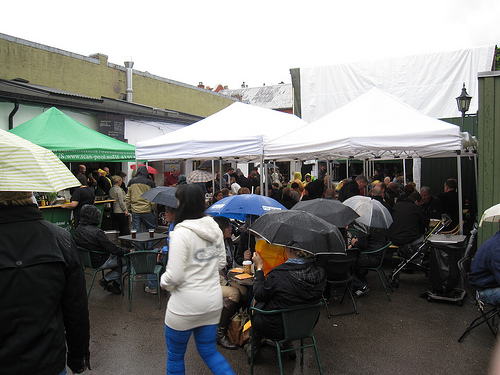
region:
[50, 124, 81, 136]
the umbrella is green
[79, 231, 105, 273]
the person is sitting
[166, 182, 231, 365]
the lady is walking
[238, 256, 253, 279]
the cup is brown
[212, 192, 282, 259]
the person is holding the umbrella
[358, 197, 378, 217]
the umbrella is gray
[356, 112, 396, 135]
the tent is white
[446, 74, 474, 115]
the light is off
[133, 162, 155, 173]
the umbrella is red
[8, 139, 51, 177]
the umbrella has stripes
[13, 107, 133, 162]
green pop up tent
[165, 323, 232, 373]
tight blue pants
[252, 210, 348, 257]
black umbrella is open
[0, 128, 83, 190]
horizontal stripes on the umbrella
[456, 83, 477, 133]
black light is not on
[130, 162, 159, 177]
small red umbrella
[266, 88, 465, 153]
white pop up tent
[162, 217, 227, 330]
white hooded sweatshirt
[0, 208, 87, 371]
black rain jacket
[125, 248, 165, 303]
empty outdoor chair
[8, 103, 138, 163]
part of top of green canopy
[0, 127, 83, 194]
part of green and white striped umbrella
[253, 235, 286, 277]
person holding orange object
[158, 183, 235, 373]
woman wearing blue leggings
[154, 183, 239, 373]
woman wearing white sweatshirt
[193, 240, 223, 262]
gray design on back of sweatshirt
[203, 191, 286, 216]
part of blue unbrella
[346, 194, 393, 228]
part of white umbrella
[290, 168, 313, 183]
heads of two people wearing yellow ponchos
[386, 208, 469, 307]
stroller behind garbage can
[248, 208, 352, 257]
Black umbrella in above the person.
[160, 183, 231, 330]
White jacket on the person.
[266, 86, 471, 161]
White canopy top in the background.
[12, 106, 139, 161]
Green canopy top in the background.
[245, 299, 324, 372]
Metal chair on the ground.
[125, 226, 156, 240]
Drinks on the table.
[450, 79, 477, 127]
Light on the building.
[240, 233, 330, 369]
Person sitting in the chair.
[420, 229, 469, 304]
Trash can beside the building.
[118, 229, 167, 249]
Black table top in the background.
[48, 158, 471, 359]
people sit around tables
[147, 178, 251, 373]
woman wears a long sleeve top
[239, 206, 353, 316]
person holding a black umbrella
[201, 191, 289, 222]
a blue umbrella with white letters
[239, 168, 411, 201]
many people on the background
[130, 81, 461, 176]
two white awnings on the street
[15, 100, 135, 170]
two green awnings on the street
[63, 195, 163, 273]
man sit in front of a table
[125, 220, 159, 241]
two glasses of beer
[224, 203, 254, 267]
a hand holding un umbrella